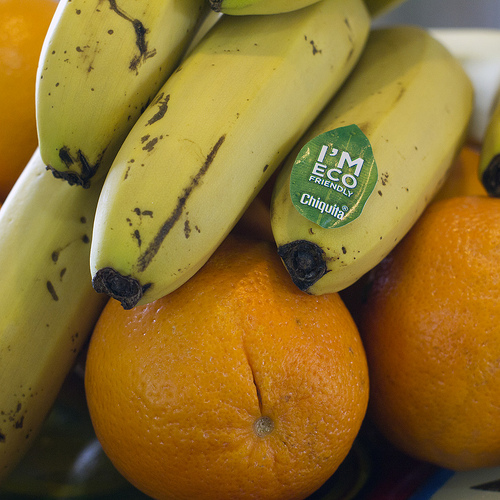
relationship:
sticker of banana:
[287, 118, 380, 231] [269, 15, 481, 288]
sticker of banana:
[287, 118, 380, 231] [35, 0, 212, 185]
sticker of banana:
[287, 118, 380, 231] [90, 0, 362, 295]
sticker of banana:
[287, 118, 380, 231] [476, 80, 499, 201]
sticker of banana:
[287, 118, 380, 231] [1, 138, 108, 494]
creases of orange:
[229, 343, 294, 487] [409, 246, 488, 391]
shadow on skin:
[367, 32, 407, 71] [221, 60, 283, 101]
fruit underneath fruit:
[85, 234, 369, 497] [362, 196, 497, 467]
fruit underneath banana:
[85, 234, 369, 497] [28, 19, 203, 146]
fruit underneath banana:
[85, 234, 369, 497] [119, 13, 366, 275]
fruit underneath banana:
[85, 234, 369, 497] [321, 14, 488, 287]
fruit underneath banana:
[85, 234, 369, 497] [7, 141, 94, 469]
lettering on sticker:
[314, 138, 368, 197] [287, 118, 380, 231]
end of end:
[279, 240, 324, 288] [94, 258, 144, 307]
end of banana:
[279, 240, 324, 288] [269, 15, 481, 288]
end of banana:
[279, 240, 324, 288] [90, 0, 362, 295]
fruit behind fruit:
[89, 3, 369, 307] [274, 21, 473, 286]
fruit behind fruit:
[33, 0, 215, 187] [274, 21, 473, 286]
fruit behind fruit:
[85, 263, 370, 498] [274, 21, 473, 286]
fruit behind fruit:
[362, 196, 497, 467] [274, 21, 473, 286]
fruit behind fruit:
[4, 142, 104, 498] [274, 21, 473, 286]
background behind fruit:
[441, 0, 484, 52] [274, 21, 473, 286]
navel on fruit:
[255, 410, 274, 440] [85, 234, 369, 497]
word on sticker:
[297, 190, 347, 220] [287, 118, 380, 231]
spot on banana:
[42, 275, 62, 305] [4, 161, 106, 481]